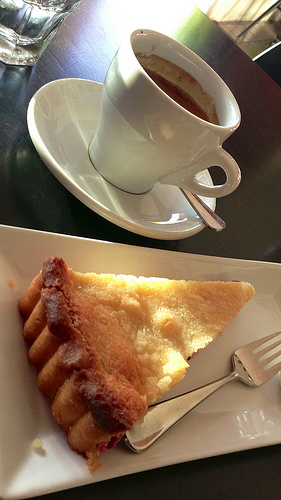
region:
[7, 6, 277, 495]
An slanted image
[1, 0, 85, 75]
Glass in left corner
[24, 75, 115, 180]
White saucer plate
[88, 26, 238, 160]
Mug for hot beverage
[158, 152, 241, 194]
Handle on mug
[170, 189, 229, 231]
A utensil next to mug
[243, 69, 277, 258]
A Black surface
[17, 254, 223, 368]
Pie with crispy crust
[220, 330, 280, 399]
Fork next to pie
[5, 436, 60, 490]
White plate holds pie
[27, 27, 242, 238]
teacup on saucer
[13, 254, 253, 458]
slice of pie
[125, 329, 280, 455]
fork on a plate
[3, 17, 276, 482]
food and beverage on white plates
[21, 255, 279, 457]
piece of pie and fork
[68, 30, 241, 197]
teacup with something in it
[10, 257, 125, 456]
crust of a pastry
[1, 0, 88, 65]
glass drinking glass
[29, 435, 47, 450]
crumb of a dessert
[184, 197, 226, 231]
handle of a spoon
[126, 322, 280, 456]
the silver fork on the plate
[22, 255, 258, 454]
a slice of pie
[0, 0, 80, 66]
a clear glass cup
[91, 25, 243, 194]
a white coffee mug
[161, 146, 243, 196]
the handle on the cup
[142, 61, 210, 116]
the brown liquid in the white cup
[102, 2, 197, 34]
the reflection on the table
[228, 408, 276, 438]
the reflection on the plate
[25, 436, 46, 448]
the crumb on the plate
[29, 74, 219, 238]
the white plate under the cup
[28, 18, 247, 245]
a cup on a small white dish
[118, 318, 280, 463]
a fork color silver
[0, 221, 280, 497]
a pie on a rectangular dish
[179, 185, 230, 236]
handle of an utensil over a dish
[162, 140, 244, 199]
handle of a cup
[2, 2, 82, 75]
a glass next to a cup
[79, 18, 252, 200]
a cup with chocolate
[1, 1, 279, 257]
a cup over a brown table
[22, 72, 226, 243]
a small white dish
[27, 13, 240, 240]
a white cup on a white plate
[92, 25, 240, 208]
a white cup of coffee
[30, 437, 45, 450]
a crumb of pie on a plate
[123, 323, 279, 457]
a stainless steel fork propped on a plate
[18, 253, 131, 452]
a baked pie crust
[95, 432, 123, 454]
a raspberry in a pie crust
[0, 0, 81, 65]
a glass of water on a table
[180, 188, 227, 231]
tip of a stainless steel teaspoon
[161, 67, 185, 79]
coffee stain on a white cup